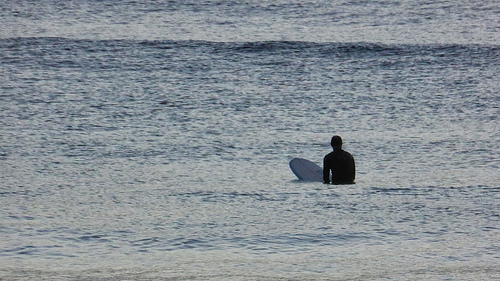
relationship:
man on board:
[329, 133, 356, 196] [289, 149, 323, 181]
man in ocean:
[329, 133, 356, 196] [114, 109, 171, 143]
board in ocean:
[289, 149, 323, 181] [114, 109, 171, 143]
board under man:
[289, 149, 323, 181] [329, 133, 356, 196]